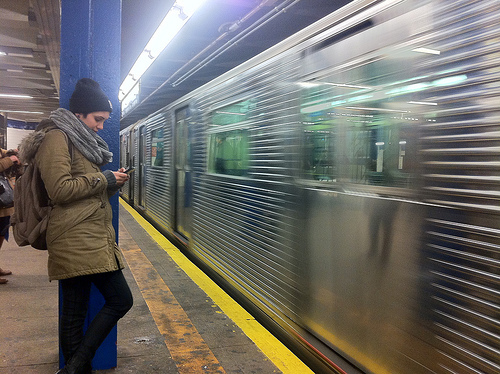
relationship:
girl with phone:
[35, 78, 133, 372] [113, 149, 138, 180]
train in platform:
[119, 0, 495, 370] [0, 5, 275, 370]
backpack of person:
[13, 162, 49, 251] [11, 81, 166, 372]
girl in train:
[35, 78, 133, 372] [160, 65, 492, 291]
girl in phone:
[35, 78, 133, 372] [111, 161, 145, 191]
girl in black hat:
[35, 78, 133, 372] [70, 72, 112, 112]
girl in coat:
[35, 78, 133, 372] [36, 134, 111, 234]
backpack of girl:
[12, 162, 44, 251] [35, 78, 133, 372]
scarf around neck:
[15, 104, 115, 167] [62, 116, 89, 145]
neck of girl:
[62, 116, 89, 145] [35, 78, 133, 372]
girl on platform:
[35, 78, 133, 372] [9, 180, 317, 372]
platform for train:
[9, 180, 317, 372] [119, 0, 495, 370]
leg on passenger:
[382, 221, 394, 270] [346, 155, 408, 262]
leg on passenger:
[361, 214, 378, 260] [346, 155, 408, 262]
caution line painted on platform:
[117, 196, 316, 372] [9, 180, 317, 372]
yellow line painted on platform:
[114, 221, 235, 374] [9, 180, 317, 372]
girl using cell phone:
[3, 72, 143, 373] [118, 160, 132, 180]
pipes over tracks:
[120, 0, 303, 122] [122, 184, 336, 372]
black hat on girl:
[70, 78, 113, 113] [35, 78, 133, 372]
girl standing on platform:
[35, 78, 133, 372] [0, 191, 318, 374]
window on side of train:
[208, 101, 249, 177] [119, 0, 495, 370]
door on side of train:
[176, 111, 191, 240] [121, 25, 481, 366]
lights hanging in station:
[113, 0, 200, 98] [5, 0, 495, 373]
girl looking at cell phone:
[35, 78, 133, 372] [116, 163, 136, 176]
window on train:
[299, 114, 424, 203] [119, 0, 495, 370]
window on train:
[149, 125, 164, 167] [119, 0, 495, 370]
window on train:
[206, 127, 248, 177] [119, 0, 495, 370]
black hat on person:
[70, 78, 113, 113] [24, 76, 139, 373]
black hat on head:
[70, 78, 113, 113] [72, 76, 109, 138]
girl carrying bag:
[35, 78, 133, 372] [5, 118, 79, 250]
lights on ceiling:
[174, 0, 201, 17] [120, 4, 263, 140]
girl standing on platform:
[35, 78, 133, 372] [1, 194, 308, 371]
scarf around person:
[49, 108, 114, 165] [14, 77, 154, 372]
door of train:
[176, 111, 197, 236] [119, 0, 495, 370]